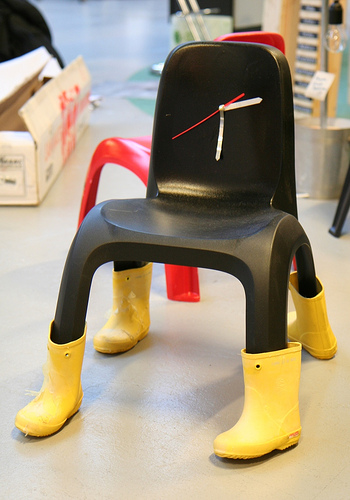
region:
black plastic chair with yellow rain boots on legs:
[16, 44, 337, 458]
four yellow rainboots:
[17, 263, 336, 459]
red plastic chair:
[82, 33, 283, 299]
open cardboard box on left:
[0, 49, 89, 207]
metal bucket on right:
[296, 118, 349, 202]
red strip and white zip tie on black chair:
[170, 92, 262, 159]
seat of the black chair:
[93, 197, 292, 241]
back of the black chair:
[141, 40, 297, 205]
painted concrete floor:
[0, 2, 347, 491]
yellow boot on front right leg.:
[13, 316, 87, 437]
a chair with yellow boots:
[38, 25, 324, 289]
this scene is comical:
[64, 124, 312, 394]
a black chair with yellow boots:
[62, 182, 347, 383]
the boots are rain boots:
[52, 261, 323, 447]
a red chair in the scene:
[71, 114, 153, 208]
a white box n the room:
[2, 42, 92, 216]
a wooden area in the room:
[280, 1, 349, 110]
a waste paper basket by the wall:
[291, 111, 345, 223]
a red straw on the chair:
[179, 81, 276, 155]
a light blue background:
[55, 6, 164, 83]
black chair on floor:
[105, 91, 307, 319]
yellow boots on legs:
[219, 327, 341, 486]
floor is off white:
[129, 379, 184, 483]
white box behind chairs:
[5, 64, 102, 198]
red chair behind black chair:
[89, 111, 206, 308]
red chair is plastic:
[104, 42, 261, 316]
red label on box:
[40, 82, 92, 169]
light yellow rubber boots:
[194, 332, 310, 445]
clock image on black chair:
[178, 86, 275, 181]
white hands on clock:
[192, 78, 273, 159]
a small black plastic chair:
[14, 41, 339, 462]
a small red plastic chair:
[75, 27, 297, 302]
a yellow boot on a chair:
[212, 338, 301, 460]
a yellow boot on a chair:
[13, 316, 88, 438]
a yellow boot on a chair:
[286, 269, 338, 361]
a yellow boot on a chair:
[91, 261, 155, 353]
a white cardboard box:
[0, 47, 94, 206]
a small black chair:
[51, 40, 319, 354]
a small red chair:
[75, 29, 297, 303]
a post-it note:
[304, 69, 338, 101]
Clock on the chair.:
[143, 52, 331, 278]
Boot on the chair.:
[206, 321, 314, 494]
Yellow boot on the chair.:
[169, 311, 280, 478]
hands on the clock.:
[166, 72, 280, 167]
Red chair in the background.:
[58, 63, 198, 232]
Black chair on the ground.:
[34, 164, 315, 393]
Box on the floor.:
[4, 43, 122, 241]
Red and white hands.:
[151, 69, 290, 195]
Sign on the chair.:
[276, 36, 340, 120]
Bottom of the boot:
[187, 422, 259, 478]